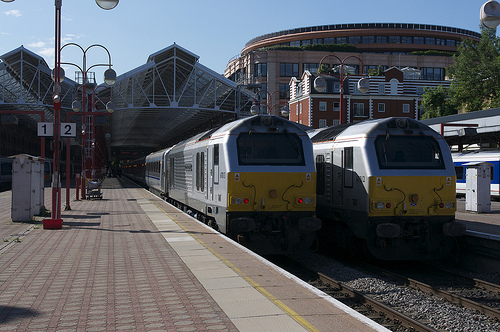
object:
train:
[114, 112, 319, 237]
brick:
[115, 272, 128, 276]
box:
[8, 152, 45, 222]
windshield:
[236, 132, 307, 167]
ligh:
[243, 198, 249, 204]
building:
[225, 11, 483, 121]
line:
[133, 185, 317, 332]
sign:
[37, 121, 53, 136]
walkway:
[0, 178, 389, 331]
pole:
[84, 44, 111, 69]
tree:
[418, 85, 458, 121]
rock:
[396, 289, 410, 298]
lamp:
[50, 43, 118, 200]